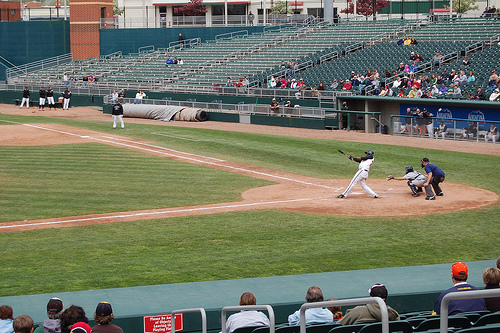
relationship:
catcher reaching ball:
[379, 157, 428, 199] [383, 169, 393, 184]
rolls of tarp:
[97, 85, 202, 131] [136, 104, 201, 124]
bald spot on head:
[309, 288, 317, 295] [303, 285, 323, 305]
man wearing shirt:
[206, 280, 273, 328] [226, 300, 288, 331]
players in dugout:
[481, 122, 498, 142] [362, 101, 498, 147]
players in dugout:
[465, 119, 479, 136] [362, 101, 498, 147]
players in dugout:
[434, 120, 449, 137] [362, 101, 498, 147]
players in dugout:
[423, 106, 435, 138] [362, 101, 498, 147]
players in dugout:
[396, 121, 410, 136] [362, 101, 498, 147]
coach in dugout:
[412, 107, 425, 138] [362, 101, 498, 147]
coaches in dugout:
[404, 107, 414, 139] [362, 101, 498, 147]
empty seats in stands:
[203, 18, 499, 36] [3, 10, 498, 103]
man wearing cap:
[429, 253, 485, 320] [451, 261, 471, 276]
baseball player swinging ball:
[337, 149, 380, 198] [385, 175, 393, 183]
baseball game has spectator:
[2, 0, 499, 330] [289, 285, 332, 324]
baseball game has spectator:
[2, 0, 497, 330] [334, 283, 401, 323]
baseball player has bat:
[337, 149, 380, 198] [337, 143, 349, 160]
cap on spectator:
[448, 258, 470, 277] [433, 252, 486, 317]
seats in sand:
[264, 55, 454, 135] [297, 133, 461, 218]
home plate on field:
[349, 184, 369, 199] [0, 102, 497, 303]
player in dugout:
[479, 120, 498, 139] [337, 91, 499, 148]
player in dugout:
[459, 122, 481, 141] [337, 91, 499, 148]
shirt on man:
[222, 304, 294, 326] [222, 288, 273, 333]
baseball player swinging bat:
[337, 144, 381, 203] [335, 148, 350, 160]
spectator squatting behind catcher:
[419, 157, 445, 201] [388, 167, 428, 197]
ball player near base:
[105, 99, 126, 133] [81, 127, 101, 149]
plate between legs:
[350, 188, 362, 200] [338, 174, 379, 199]